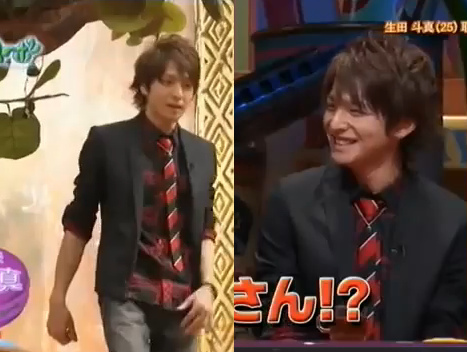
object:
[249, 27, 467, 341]
man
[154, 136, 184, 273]
tie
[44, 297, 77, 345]
left hand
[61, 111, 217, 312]
coat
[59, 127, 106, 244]
sleeves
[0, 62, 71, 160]
tree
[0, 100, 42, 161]
leaf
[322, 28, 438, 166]
head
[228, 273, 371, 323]
writing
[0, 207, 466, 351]
front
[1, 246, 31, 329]
symbols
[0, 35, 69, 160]
design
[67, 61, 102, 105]
wall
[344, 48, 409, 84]
hair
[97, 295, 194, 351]
jeans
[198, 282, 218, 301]
watch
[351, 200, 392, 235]
necklace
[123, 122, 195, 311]
shirt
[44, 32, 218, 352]
man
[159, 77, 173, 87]
eyes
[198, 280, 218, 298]
bracelet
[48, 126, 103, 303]
arm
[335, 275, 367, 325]
words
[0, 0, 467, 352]
screen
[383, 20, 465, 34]
characters